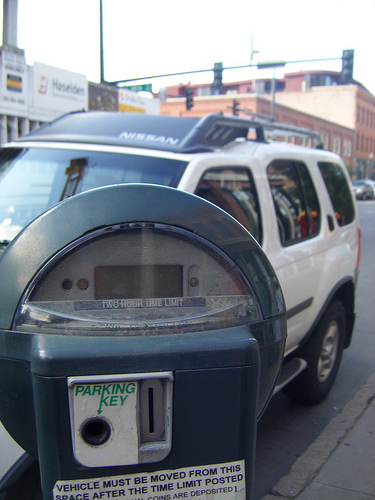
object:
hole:
[73, 408, 114, 450]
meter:
[0, 174, 294, 500]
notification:
[93, 289, 187, 310]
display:
[93, 262, 184, 300]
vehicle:
[0, 104, 365, 468]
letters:
[74, 379, 136, 414]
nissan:
[119, 124, 176, 152]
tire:
[284, 296, 345, 409]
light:
[354, 225, 363, 273]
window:
[264, 149, 324, 255]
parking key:
[63, 383, 139, 413]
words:
[69, 375, 137, 418]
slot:
[139, 384, 160, 440]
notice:
[44, 456, 247, 500]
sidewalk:
[274, 372, 375, 497]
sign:
[99, 296, 180, 335]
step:
[274, 344, 309, 390]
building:
[157, 48, 374, 190]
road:
[259, 401, 375, 497]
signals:
[334, 46, 360, 81]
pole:
[97, 1, 107, 86]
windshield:
[0, 145, 188, 202]